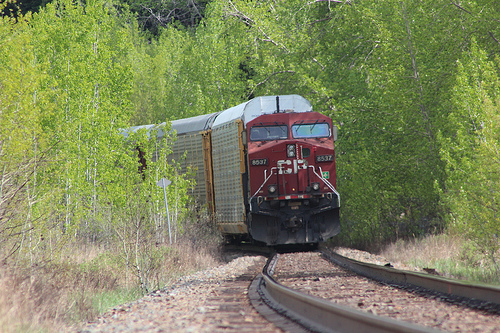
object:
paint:
[244, 108, 339, 201]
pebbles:
[76, 254, 261, 331]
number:
[315, 154, 332, 162]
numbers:
[250, 158, 270, 167]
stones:
[115, 278, 191, 312]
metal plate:
[246, 190, 348, 247]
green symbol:
[319, 169, 329, 180]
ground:
[410, 180, 433, 195]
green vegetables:
[243, 250, 406, 326]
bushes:
[2, 137, 162, 296]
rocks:
[80, 255, 282, 331]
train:
[115, 87, 350, 258]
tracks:
[260, 239, 496, 331]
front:
[248, 106, 343, 255]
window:
[247, 124, 287, 141]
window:
[290, 122, 332, 138]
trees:
[1, 5, 498, 252]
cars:
[151, 89, 343, 248]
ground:
[81, 247, 494, 329]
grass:
[6, 234, 209, 327]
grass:
[412, 250, 497, 284]